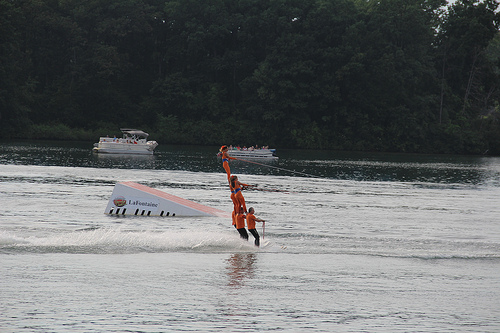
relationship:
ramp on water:
[105, 179, 231, 219] [3, 144, 495, 328]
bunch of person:
[109, 139, 145, 146] [109, 136, 116, 143]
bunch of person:
[109, 139, 145, 146] [114, 139, 121, 143]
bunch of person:
[109, 139, 145, 146] [126, 139, 128, 143]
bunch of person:
[109, 139, 145, 146] [129, 139, 133, 146]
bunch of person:
[109, 139, 145, 146] [133, 141, 137, 148]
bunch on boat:
[109, 139, 145, 146] [92, 125, 157, 157]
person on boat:
[109, 136, 116, 143] [92, 125, 157, 157]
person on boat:
[114, 139, 121, 143] [92, 125, 157, 157]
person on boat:
[126, 139, 128, 143] [92, 125, 157, 157]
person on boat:
[129, 139, 133, 146] [92, 125, 157, 157]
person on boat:
[133, 141, 137, 148] [92, 125, 157, 157]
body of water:
[2, 136, 496, 329] [3, 144, 495, 328]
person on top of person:
[218, 142, 235, 168] [229, 174, 244, 196]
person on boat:
[111, 136, 113, 145] [91, 126, 159, 156]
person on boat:
[116, 137, 118, 142] [91, 126, 159, 156]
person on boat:
[123, 137, 130, 142] [91, 126, 159, 156]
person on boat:
[235, 145, 239, 150] [217, 142, 279, 160]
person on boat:
[242, 146, 246, 150] [217, 142, 279, 160]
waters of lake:
[38, 244, 488, 327] [3, 136, 497, 329]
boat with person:
[92, 128, 159, 154] [111, 134, 115, 144]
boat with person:
[92, 128, 159, 154] [115, 139, 119, 143]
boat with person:
[92, 128, 159, 154] [122, 139, 129, 146]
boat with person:
[92, 128, 159, 154] [127, 139, 134, 146]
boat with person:
[92, 128, 159, 154] [134, 139, 139, 146]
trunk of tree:
[462, 62, 477, 118] [432, 4, 498, 110]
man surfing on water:
[246, 208, 263, 244] [350, 150, 453, 287]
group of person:
[220, 143, 268, 246] [247, 210, 267, 246]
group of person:
[220, 143, 268, 246] [235, 210, 249, 241]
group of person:
[220, 143, 268, 246] [231, 179, 252, 205]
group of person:
[220, 143, 268, 246] [223, 181, 239, 212]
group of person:
[220, 143, 268, 246] [216, 143, 232, 179]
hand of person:
[245, 183, 279, 191] [231, 174, 257, 213]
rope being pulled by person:
[231, 147, 497, 274] [218, 142, 235, 168]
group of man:
[220, 143, 268, 246] [246, 208, 263, 244]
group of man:
[220, 143, 268, 246] [236, 208, 250, 244]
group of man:
[220, 143, 268, 246] [229, 208, 239, 238]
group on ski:
[220, 143, 268, 246] [263, 242, 270, 252]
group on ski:
[220, 143, 268, 246] [261, 239, 268, 246]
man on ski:
[246, 208, 263, 244] [263, 242, 270, 252]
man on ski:
[246, 208, 263, 244] [261, 239, 268, 246]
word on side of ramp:
[125, 196, 158, 210] [105, 179, 231, 219]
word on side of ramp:
[111, 208, 178, 219] [105, 179, 231, 219]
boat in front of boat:
[92, 128, 159, 154] [215, 136, 279, 161]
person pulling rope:
[218, 142, 235, 168] [231, 147, 497, 274]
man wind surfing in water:
[246, 206, 262, 247] [3, 144, 495, 328]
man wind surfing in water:
[236, 208, 250, 240] [3, 144, 495, 328]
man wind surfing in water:
[232, 210, 242, 238] [3, 144, 495, 328]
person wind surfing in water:
[231, 179, 255, 205] [3, 144, 495, 328]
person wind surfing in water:
[218, 142, 235, 168] [3, 144, 495, 328]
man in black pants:
[246, 206, 262, 247] [246, 231, 260, 250]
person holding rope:
[218, 142, 235, 168] [233, 156, 477, 213]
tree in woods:
[421, 20, 454, 150] [5, 5, 497, 127]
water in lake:
[3, 144, 495, 328] [3, 136, 497, 329]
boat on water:
[211, 127, 287, 164] [3, 144, 495, 328]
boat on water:
[87, 120, 168, 158] [3, 144, 495, 328]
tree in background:
[71, 42, 129, 139] [3, 3, 497, 148]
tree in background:
[154, 42, 224, 143] [3, 3, 497, 148]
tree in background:
[258, 30, 336, 153] [3, 3, 497, 148]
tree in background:
[343, 49, 439, 153] [3, 3, 497, 148]